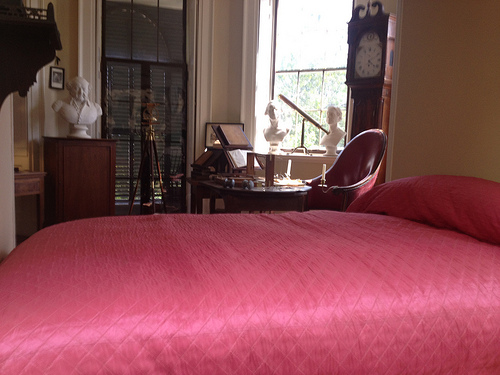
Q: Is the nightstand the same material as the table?
A: Yes, both the nightstand and the table are made of wood.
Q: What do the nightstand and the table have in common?
A: The material, both the nightstand and the table are wooden.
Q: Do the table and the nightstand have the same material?
A: Yes, both the table and the nightstand are made of wood.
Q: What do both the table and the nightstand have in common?
A: The material, both the table and the nightstand are wooden.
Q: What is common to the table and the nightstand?
A: The material, both the table and the nightstand are wooden.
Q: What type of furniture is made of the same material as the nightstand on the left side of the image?
A: The table is made of the same material as the nightstand.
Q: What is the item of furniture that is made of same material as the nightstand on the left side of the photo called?
A: The piece of furniture is a table.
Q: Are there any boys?
A: No, there are no boys.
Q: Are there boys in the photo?
A: No, there are no boys.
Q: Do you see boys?
A: No, there are no boys.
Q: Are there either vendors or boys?
A: No, there are no boys or vendors.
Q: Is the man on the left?
A: Yes, the man is on the left of the image.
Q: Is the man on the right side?
A: No, the man is on the left of the image.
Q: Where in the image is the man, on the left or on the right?
A: The man is on the left of the image.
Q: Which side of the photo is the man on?
A: The man is on the left of the image.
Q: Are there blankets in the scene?
A: Yes, there is a blanket.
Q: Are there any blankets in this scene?
A: Yes, there is a blanket.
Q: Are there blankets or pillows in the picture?
A: Yes, there is a blanket.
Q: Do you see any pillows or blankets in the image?
A: Yes, there is a blanket.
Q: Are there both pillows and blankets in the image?
A: Yes, there are both a blanket and pillows.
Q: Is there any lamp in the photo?
A: No, there are no lamps.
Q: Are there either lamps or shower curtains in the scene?
A: No, there are no lamps or shower curtains.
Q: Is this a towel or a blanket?
A: This is a blanket.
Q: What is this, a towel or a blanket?
A: This is a blanket.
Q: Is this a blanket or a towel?
A: This is a blanket.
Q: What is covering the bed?
A: The blanket is covering the bed.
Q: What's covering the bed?
A: The blanket is covering the bed.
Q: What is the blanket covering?
A: The blanket is covering the bed.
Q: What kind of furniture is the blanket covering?
A: The blanket is covering the bed.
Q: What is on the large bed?
A: The blanket is on the bed.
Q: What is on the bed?
A: The blanket is on the bed.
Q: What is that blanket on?
A: The blanket is on the bed.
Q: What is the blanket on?
A: The blanket is on the bed.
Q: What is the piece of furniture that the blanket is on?
A: The piece of furniture is a bed.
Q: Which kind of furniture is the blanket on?
A: The blanket is on the bed.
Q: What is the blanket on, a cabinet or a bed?
A: The blanket is on a bed.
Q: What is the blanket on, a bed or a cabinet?
A: The blanket is on a bed.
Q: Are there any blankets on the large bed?
A: Yes, there is a blanket on the bed.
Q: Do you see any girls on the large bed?
A: No, there is a blanket on the bed.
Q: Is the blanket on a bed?
A: Yes, the blanket is on a bed.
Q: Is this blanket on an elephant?
A: No, the blanket is on a bed.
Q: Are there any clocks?
A: Yes, there is a clock.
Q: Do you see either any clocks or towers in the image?
A: Yes, there is a clock.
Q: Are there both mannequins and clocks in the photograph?
A: No, there is a clock but no mannequins.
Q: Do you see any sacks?
A: No, there are no sacks.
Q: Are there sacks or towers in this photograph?
A: No, there are no sacks or towers.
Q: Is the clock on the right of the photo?
A: Yes, the clock is on the right of the image.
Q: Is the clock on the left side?
A: No, the clock is on the right of the image.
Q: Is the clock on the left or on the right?
A: The clock is on the right of the image.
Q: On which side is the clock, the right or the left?
A: The clock is on the right of the image.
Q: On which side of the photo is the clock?
A: The clock is on the right of the image.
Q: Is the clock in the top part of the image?
A: Yes, the clock is in the top of the image.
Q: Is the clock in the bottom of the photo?
A: No, the clock is in the top of the image.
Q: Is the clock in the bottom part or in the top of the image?
A: The clock is in the top of the image.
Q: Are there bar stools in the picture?
A: No, there are no bar stools.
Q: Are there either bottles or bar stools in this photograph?
A: No, there are no bar stools or bottles.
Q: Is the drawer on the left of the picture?
A: Yes, the drawer is on the left of the image.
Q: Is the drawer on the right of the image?
A: No, the drawer is on the left of the image.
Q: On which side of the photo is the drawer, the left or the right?
A: The drawer is on the left of the image.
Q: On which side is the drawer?
A: The drawer is on the left of the image.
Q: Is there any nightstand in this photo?
A: Yes, there is a nightstand.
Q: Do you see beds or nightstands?
A: Yes, there is a nightstand.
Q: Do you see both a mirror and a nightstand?
A: No, there is a nightstand but no mirrors.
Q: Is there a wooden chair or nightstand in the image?
A: Yes, there is a wood nightstand.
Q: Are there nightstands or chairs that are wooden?
A: Yes, the nightstand is wooden.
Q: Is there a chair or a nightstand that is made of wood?
A: Yes, the nightstand is made of wood.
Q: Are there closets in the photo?
A: No, there are no closets.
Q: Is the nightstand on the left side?
A: Yes, the nightstand is on the left of the image.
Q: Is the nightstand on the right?
A: No, the nightstand is on the left of the image.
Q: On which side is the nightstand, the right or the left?
A: The nightstand is on the left of the image.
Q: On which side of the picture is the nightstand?
A: The nightstand is on the left of the image.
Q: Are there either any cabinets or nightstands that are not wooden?
A: No, there is a nightstand but it is wooden.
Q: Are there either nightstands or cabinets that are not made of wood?
A: No, there is a nightstand but it is made of wood.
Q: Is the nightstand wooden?
A: Yes, the nightstand is wooden.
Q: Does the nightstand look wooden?
A: Yes, the nightstand is wooden.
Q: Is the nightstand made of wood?
A: Yes, the nightstand is made of wood.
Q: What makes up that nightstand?
A: The nightstand is made of wood.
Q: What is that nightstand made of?
A: The nightstand is made of wood.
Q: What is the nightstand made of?
A: The nightstand is made of wood.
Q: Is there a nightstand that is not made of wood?
A: No, there is a nightstand but it is made of wood.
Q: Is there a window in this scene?
A: Yes, there is a window.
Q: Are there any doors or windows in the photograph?
A: Yes, there is a window.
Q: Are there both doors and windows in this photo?
A: No, there is a window but no doors.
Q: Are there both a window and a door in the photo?
A: No, there is a window but no doors.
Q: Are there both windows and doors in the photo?
A: No, there is a window but no doors.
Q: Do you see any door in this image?
A: No, there are no doors.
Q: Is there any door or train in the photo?
A: No, there are no doors or trains.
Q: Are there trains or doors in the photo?
A: No, there are no doors or trains.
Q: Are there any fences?
A: No, there are no fences.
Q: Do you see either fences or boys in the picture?
A: No, there are no fences or boys.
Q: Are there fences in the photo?
A: No, there are no fences.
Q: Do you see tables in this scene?
A: Yes, there is a table.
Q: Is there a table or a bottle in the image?
A: Yes, there is a table.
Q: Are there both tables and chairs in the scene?
A: Yes, there are both a table and a chair.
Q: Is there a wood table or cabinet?
A: Yes, there is a wood table.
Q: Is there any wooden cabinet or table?
A: Yes, there is a wood table.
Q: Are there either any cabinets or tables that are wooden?
A: Yes, the table is wooden.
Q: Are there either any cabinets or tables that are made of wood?
A: Yes, the table is made of wood.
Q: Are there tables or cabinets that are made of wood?
A: Yes, the table is made of wood.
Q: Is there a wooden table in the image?
A: Yes, there is a wood table.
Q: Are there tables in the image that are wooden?
A: Yes, there is a table that is wooden.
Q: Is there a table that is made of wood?
A: Yes, there is a table that is made of wood.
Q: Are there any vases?
A: No, there are no vases.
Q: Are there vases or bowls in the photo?
A: No, there are no vases or bowls.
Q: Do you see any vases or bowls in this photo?
A: No, there are no vases or bowls.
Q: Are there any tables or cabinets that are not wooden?
A: No, there is a table but it is wooden.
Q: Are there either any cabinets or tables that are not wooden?
A: No, there is a table but it is wooden.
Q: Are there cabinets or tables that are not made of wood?
A: No, there is a table but it is made of wood.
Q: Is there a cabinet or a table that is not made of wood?
A: No, there is a table but it is made of wood.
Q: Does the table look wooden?
A: Yes, the table is wooden.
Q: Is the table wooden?
A: Yes, the table is wooden.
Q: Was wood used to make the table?
A: Yes, the table is made of wood.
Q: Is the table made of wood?
A: Yes, the table is made of wood.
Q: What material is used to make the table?
A: The table is made of wood.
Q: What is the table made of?
A: The table is made of wood.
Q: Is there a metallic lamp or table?
A: No, there is a table but it is wooden.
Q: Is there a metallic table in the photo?
A: No, there is a table but it is wooden.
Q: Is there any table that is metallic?
A: No, there is a table but it is wooden.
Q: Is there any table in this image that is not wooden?
A: No, there is a table but it is wooden.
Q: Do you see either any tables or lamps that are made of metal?
A: No, there is a table but it is made of wood.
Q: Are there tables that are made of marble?
A: No, there is a table but it is made of wood.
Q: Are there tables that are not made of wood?
A: No, there is a table but it is made of wood.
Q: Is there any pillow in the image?
A: Yes, there is a pillow.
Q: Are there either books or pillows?
A: Yes, there is a pillow.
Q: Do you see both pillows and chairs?
A: Yes, there are both a pillow and a chair.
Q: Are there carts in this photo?
A: No, there are no carts.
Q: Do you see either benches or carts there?
A: No, there are no carts or benches.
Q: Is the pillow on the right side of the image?
A: Yes, the pillow is on the right of the image.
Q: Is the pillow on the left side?
A: No, the pillow is on the right of the image.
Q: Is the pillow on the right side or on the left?
A: The pillow is on the right of the image.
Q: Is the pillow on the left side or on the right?
A: The pillow is on the right of the image.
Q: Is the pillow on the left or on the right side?
A: The pillow is on the right of the image.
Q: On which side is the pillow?
A: The pillow is on the right of the image.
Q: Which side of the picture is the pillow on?
A: The pillow is on the right of the image.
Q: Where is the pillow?
A: The pillow is at the bed.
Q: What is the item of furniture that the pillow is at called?
A: The piece of furniture is a bed.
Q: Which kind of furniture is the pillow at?
A: The pillow is at the bed.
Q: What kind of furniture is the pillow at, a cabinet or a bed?
A: The pillow is at a bed.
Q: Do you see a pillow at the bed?
A: Yes, there is a pillow at the bed.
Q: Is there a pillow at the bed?
A: Yes, there is a pillow at the bed.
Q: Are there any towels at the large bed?
A: No, there is a pillow at the bed.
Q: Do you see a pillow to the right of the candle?
A: Yes, there is a pillow to the right of the candle.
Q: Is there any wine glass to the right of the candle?
A: No, there is a pillow to the right of the candle.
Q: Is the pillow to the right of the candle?
A: Yes, the pillow is to the right of the candle.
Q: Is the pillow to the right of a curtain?
A: No, the pillow is to the right of the candle.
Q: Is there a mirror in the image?
A: No, there are no mirrors.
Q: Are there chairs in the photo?
A: Yes, there is a chair.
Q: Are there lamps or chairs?
A: Yes, there is a chair.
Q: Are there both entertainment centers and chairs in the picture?
A: No, there is a chair but no entertainment centers.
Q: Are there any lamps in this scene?
A: No, there are no lamps.